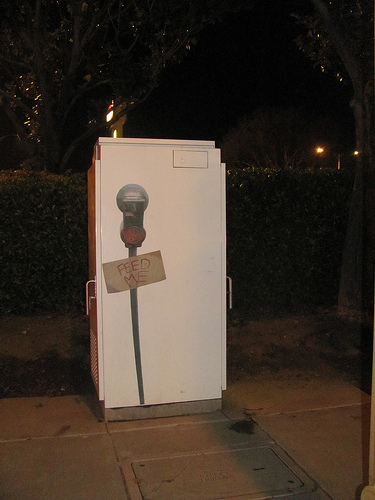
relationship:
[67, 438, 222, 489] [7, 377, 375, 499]
part of path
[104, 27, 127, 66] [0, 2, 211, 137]
part of tree branches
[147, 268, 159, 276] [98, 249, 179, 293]
part of poster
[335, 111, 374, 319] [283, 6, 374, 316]
stem of tree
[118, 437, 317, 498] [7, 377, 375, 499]
panel on sidewalk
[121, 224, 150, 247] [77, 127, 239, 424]
handle on structure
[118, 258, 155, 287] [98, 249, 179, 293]
writing on sign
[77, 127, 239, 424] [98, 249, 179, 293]
box with sign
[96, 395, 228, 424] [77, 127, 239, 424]
bottom of box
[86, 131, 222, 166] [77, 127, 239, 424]
top of box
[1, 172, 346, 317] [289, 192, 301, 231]
fence of leaves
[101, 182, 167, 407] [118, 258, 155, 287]
cardboard with writing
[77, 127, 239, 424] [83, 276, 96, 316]
both with handle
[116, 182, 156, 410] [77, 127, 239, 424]
sticker on locker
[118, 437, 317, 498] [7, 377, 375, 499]
access lid on sidewalk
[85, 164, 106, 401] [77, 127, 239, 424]
door of electrical box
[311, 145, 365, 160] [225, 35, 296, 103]
street light at night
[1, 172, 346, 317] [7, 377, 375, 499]
shrubs beside sidewalk